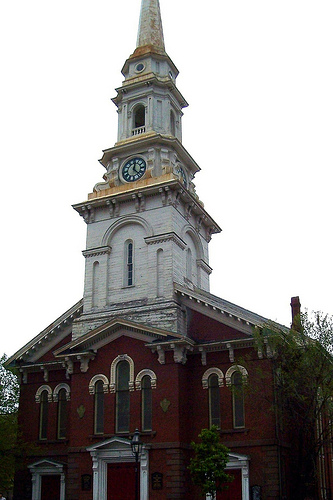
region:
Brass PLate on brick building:
[154, 394, 173, 416]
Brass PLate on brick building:
[71, 398, 89, 419]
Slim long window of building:
[117, 234, 137, 292]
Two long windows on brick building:
[193, 367, 259, 433]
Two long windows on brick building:
[26, 383, 77, 441]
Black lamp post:
[123, 425, 154, 475]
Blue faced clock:
[117, 155, 165, 185]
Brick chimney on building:
[274, 278, 313, 342]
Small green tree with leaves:
[191, 420, 232, 496]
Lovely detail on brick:
[80, 359, 160, 403]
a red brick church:
[1, 1, 327, 495]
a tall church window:
[113, 355, 132, 431]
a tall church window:
[136, 372, 154, 432]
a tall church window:
[93, 376, 106, 432]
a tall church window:
[56, 388, 66, 438]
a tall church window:
[37, 387, 50, 439]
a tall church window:
[207, 372, 220, 428]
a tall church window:
[228, 371, 246, 426]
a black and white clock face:
[118, 156, 145, 181]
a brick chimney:
[288, 293, 300, 328]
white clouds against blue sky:
[3, 19, 50, 60]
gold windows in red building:
[90, 359, 159, 441]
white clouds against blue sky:
[50, 38, 96, 78]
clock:
[113, 153, 153, 183]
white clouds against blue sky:
[4, 180, 61, 224]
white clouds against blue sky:
[214, 39, 268, 67]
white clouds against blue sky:
[236, 113, 308, 174]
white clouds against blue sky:
[233, 212, 296, 258]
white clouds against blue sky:
[212, 150, 273, 216]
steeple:
[121, 12, 173, 55]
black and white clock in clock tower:
[118, 153, 152, 178]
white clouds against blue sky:
[20, 55, 68, 112]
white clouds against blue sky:
[19, 166, 49, 206]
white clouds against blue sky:
[233, 252, 265, 281]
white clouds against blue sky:
[237, 192, 285, 244]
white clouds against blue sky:
[228, 179, 264, 215]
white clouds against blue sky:
[7, 151, 53, 214]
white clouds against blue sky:
[26, 106, 86, 166]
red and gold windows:
[78, 328, 175, 430]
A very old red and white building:
[4, 0, 331, 499]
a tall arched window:
[111, 351, 135, 434]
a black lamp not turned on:
[128, 429, 142, 499]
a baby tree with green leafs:
[188, 424, 230, 499]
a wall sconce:
[158, 394, 170, 411]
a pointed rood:
[58, 312, 185, 362]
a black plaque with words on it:
[148, 464, 167, 495]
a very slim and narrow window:
[119, 237, 140, 288]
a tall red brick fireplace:
[283, 291, 309, 328]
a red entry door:
[106, 461, 139, 499]